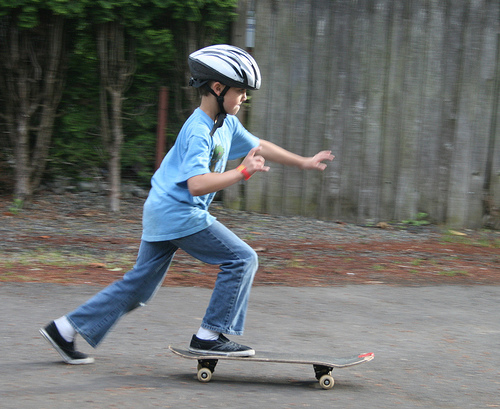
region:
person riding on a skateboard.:
[46, 25, 419, 395]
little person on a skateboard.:
[37, 27, 423, 392]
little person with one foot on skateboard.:
[33, 30, 414, 397]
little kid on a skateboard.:
[20, 12, 430, 400]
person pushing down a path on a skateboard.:
[26, 24, 419, 395]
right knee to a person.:
[209, 240, 283, 307]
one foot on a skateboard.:
[130, 326, 401, 383]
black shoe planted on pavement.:
[35, 305, 119, 373]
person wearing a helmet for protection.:
[165, 35, 271, 130]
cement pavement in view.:
[282, 282, 485, 349]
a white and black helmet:
[176, 39, 276, 101]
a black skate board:
[157, 337, 392, 387]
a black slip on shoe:
[173, 330, 255, 359]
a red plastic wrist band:
[226, 147, 254, 184]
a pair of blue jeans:
[66, 201, 297, 341]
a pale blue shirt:
[135, 94, 260, 262]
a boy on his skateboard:
[23, 15, 492, 402]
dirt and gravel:
[272, 222, 444, 279]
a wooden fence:
[342, 21, 492, 228]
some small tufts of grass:
[425, 222, 497, 257]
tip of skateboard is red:
[358, 350, 375, 362]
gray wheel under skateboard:
[318, 372, 335, 390]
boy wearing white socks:
[194, 323, 220, 338]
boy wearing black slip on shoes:
[188, 334, 253, 354]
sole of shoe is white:
[190, 345, 256, 355]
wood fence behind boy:
[226, 1, 491, 226]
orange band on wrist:
[235, 161, 252, 181]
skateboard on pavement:
[170, 335, 373, 386]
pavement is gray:
[2, 282, 497, 404]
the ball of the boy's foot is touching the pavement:
[40, 320, 94, 364]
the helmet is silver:
[182, 40, 281, 100]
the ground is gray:
[331, 310, 387, 340]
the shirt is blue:
[141, 104, 261, 254]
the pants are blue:
[67, 218, 259, 363]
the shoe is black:
[32, 299, 107, 394]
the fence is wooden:
[363, 47, 451, 200]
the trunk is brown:
[20, 32, 105, 202]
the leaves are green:
[112, 20, 174, 67]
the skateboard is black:
[165, 326, 384, 400]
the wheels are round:
[180, 358, 349, 406]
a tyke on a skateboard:
[39, 41, 376, 387]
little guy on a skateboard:
[39, 42, 376, 388]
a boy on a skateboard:
[38, 42, 378, 397]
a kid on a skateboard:
[35, 46, 378, 400]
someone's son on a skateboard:
[38, 43, 378, 391]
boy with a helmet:
[180, 41, 267, 136]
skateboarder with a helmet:
[181, 38, 264, 126]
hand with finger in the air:
[216, 136, 273, 198]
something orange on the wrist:
[233, 160, 254, 186]